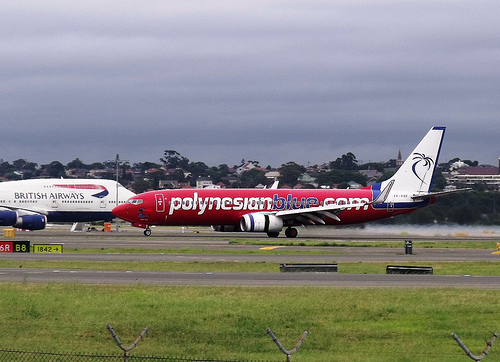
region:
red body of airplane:
[110, 185, 371, 225]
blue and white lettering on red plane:
[165, 185, 362, 217]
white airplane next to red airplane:
[5, 172, 125, 223]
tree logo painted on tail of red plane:
[412, 149, 431, 183]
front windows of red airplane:
[125, 195, 140, 204]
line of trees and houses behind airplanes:
[3, 144, 486, 203]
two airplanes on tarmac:
[5, 126, 474, 237]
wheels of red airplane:
[141, 225, 297, 241]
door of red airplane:
[153, 195, 163, 210]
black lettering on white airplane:
[11, 187, 86, 203]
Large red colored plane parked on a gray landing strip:
[113, 190, 383, 240]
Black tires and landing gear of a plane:
[136, 223, 307, 238]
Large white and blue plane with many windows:
[1, 169, 125, 229]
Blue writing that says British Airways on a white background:
[9, 185, 89, 203]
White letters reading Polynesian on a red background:
[167, 189, 273, 214]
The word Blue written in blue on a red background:
[273, 192, 319, 211]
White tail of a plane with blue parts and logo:
[353, 114, 453, 212]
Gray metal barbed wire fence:
[3, 322, 498, 360]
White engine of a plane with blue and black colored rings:
[243, 210, 287, 232]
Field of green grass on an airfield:
[85, 243, 470, 334]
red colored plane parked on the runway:
[109, 124, 466, 238]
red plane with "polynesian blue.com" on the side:
[105, 127, 471, 237]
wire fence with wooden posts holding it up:
[3, 322, 497, 360]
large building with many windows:
[448, 162, 498, 191]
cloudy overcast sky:
[3, 1, 498, 168]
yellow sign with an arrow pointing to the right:
[32, 240, 62, 255]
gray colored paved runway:
[2, 265, 497, 293]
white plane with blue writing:
[0, 177, 140, 230]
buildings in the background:
[6, 158, 498, 190]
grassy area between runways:
[2, 255, 497, 275]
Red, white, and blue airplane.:
[121, 123, 453, 243]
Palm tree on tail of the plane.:
[408, 148, 432, 185]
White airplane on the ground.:
[0, 167, 137, 233]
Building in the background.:
[442, 160, 498, 192]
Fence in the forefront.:
[2, 312, 498, 359]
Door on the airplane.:
[153, 189, 164, 213]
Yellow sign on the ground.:
[33, 240, 65, 254]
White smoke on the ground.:
[322, 219, 497, 238]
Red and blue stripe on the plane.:
[50, 180, 115, 197]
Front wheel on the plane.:
[140, 223, 152, 235]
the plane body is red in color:
[109, 178, 419, 227]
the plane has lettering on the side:
[169, 191, 371, 216]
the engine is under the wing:
[241, 213, 286, 233]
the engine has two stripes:
[248, 210, 271, 230]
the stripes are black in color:
[243, 211, 278, 231]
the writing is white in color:
[168, 193, 272, 219]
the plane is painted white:
[1, 175, 138, 222]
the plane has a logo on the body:
[51, 183, 109, 199]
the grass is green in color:
[6, 275, 499, 360]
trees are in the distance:
[9, 153, 489, 190]